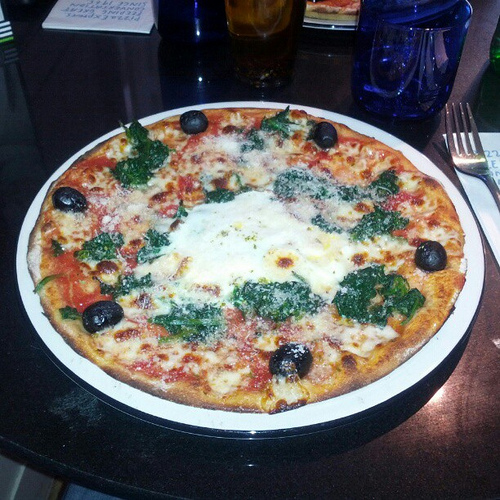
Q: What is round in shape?
A: Pizza.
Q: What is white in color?
A: The plate.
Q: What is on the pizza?
A: Cheese.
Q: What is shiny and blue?
A: Glass.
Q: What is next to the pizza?
A: A fork.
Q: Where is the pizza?
A: On the plate.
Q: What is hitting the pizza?
A: Light.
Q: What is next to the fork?
A: The pizza.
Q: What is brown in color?
A: The crust.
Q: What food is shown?
A: Pizza.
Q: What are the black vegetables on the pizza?
A: Olives.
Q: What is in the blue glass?
A: Nothing.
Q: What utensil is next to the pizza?
A: Fork.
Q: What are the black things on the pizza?
A: Olives.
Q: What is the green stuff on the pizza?
A: Spinach.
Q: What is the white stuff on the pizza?
A: Cheese.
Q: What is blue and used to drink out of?
A: Cup.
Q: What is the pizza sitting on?
A: A plate.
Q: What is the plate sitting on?
A: A table.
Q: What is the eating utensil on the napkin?
A: A fork.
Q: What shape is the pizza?
A: A circle.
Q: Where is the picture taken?
A: Restaurant.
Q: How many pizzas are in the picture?
A: One.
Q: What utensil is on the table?
A: Fork.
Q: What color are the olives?
A: Black.